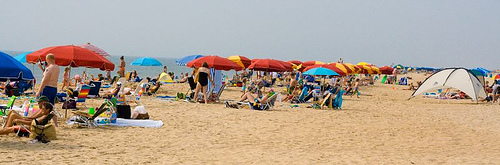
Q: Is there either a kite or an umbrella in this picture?
A: Yes, there is an umbrella.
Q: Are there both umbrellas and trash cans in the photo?
A: No, there is an umbrella but no trash cans.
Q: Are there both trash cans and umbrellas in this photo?
A: No, there is an umbrella but no trash cans.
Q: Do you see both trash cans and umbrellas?
A: No, there is an umbrella but no trash cans.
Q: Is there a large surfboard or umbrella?
A: Yes, there is a large umbrella.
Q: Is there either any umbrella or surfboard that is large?
A: Yes, the umbrella is large.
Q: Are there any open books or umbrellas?
A: Yes, there is an open umbrella.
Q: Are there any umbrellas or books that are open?
A: Yes, the umbrella is open.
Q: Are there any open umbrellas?
A: Yes, there is an open umbrella.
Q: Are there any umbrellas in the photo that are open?
A: Yes, there is an umbrella that is open.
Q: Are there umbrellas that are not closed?
A: Yes, there is a open umbrella.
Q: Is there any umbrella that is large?
A: Yes, there is an umbrella that is large.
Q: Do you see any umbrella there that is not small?
A: Yes, there is a large umbrella.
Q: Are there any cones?
A: No, there are no cones.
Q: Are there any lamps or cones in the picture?
A: No, there are no cones or lamps.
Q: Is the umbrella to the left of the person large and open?
A: Yes, the umbrella is large and open.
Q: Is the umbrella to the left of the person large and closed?
A: No, the umbrella is large but open.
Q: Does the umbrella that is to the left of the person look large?
A: Yes, the umbrella is large.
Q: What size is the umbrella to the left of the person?
A: The umbrella is large.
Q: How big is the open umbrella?
A: The umbrella is large.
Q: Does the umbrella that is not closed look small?
A: No, the umbrella is large.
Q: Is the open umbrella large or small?
A: The umbrella is large.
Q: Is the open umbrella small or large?
A: The umbrella is large.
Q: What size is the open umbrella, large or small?
A: The umbrella is large.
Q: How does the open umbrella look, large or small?
A: The umbrella is large.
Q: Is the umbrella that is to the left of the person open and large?
A: Yes, the umbrella is open and large.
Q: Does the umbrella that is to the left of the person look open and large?
A: Yes, the umbrella is open and large.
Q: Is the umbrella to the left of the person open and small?
A: No, the umbrella is open but large.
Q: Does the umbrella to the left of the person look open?
A: Yes, the umbrella is open.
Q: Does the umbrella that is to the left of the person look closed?
A: No, the umbrella is open.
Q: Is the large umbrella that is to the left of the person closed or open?
A: The umbrella is open.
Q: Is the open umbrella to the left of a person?
A: Yes, the umbrella is to the left of a person.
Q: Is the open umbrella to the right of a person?
A: No, the umbrella is to the left of a person.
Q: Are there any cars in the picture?
A: No, there are no cars.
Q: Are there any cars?
A: No, there are no cars.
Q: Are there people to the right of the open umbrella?
A: Yes, there is a person to the right of the umbrella.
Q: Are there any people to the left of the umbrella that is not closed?
A: No, the person is to the right of the umbrella.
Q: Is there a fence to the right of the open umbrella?
A: No, there is a person to the right of the umbrella.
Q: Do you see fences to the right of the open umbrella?
A: No, there is a person to the right of the umbrella.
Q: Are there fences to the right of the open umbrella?
A: No, there is a person to the right of the umbrella.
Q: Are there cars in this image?
A: No, there are no cars.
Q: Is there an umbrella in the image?
A: Yes, there is an umbrella.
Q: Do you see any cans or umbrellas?
A: Yes, there is an umbrella.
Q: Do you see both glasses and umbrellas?
A: No, there is an umbrella but no glasses.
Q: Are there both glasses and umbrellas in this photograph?
A: No, there is an umbrella but no glasses.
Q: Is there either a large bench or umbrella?
A: Yes, there is a large umbrella.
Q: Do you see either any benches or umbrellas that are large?
A: Yes, the umbrella is large.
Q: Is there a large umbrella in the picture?
A: Yes, there is a large umbrella.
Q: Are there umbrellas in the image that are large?
A: Yes, there is an umbrella that is large.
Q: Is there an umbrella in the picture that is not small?
A: Yes, there is a large umbrella.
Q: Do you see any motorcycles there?
A: No, there are no motorcycles.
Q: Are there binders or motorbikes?
A: No, there are no motorbikes or binders.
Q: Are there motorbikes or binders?
A: No, there are no motorbikes or binders.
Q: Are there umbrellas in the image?
A: Yes, there is an umbrella.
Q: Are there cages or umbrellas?
A: Yes, there is an umbrella.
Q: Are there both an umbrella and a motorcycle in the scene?
A: No, there is an umbrella but no motorcycles.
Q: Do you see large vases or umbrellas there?
A: Yes, there is a large umbrella.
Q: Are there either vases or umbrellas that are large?
A: Yes, the umbrella is large.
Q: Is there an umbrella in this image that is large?
A: Yes, there is a large umbrella.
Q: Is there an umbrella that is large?
A: Yes, there is an umbrella that is large.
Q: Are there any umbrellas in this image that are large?
A: Yes, there is an umbrella that is large.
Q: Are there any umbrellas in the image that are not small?
A: Yes, there is a large umbrella.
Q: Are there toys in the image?
A: No, there are no toys.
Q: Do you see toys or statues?
A: No, there are no toys or statues.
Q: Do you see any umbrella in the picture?
A: Yes, there is an umbrella.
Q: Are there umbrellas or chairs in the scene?
A: Yes, there is an umbrella.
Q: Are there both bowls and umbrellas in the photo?
A: No, there is an umbrella but no bowls.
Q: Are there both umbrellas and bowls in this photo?
A: No, there is an umbrella but no bowls.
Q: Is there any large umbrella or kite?
A: Yes, there is a large umbrella.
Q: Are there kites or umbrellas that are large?
A: Yes, the umbrella is large.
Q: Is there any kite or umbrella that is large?
A: Yes, the umbrella is large.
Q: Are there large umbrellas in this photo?
A: Yes, there is a large umbrella.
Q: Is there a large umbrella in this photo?
A: Yes, there is a large umbrella.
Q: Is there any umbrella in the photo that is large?
A: Yes, there is an umbrella that is large.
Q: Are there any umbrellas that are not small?
A: Yes, there is a large umbrella.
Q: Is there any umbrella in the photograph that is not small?
A: Yes, there is a large umbrella.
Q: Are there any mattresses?
A: No, there are no mattresses.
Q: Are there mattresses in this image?
A: No, there are no mattresses.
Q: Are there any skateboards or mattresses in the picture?
A: No, there are no mattresses or skateboards.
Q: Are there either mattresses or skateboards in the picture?
A: No, there are no mattresses or skateboards.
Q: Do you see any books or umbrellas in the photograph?
A: Yes, there is an umbrella.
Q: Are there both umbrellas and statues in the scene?
A: No, there is an umbrella but no statues.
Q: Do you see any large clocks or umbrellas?
A: Yes, there is a large umbrella.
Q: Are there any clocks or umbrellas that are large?
A: Yes, the umbrella is large.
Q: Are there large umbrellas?
A: Yes, there is a large umbrella.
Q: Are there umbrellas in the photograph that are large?
A: Yes, there is an umbrella that is large.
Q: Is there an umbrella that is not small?
A: Yes, there is a large umbrella.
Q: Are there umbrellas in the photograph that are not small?
A: Yes, there is a large umbrella.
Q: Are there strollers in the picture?
A: No, there are no strollers.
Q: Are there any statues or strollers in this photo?
A: No, there are no strollers or statues.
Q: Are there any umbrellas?
A: Yes, there is an umbrella.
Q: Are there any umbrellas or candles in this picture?
A: Yes, there is an umbrella.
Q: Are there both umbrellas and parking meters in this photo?
A: No, there is an umbrella but no parking meters.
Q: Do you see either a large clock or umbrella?
A: Yes, there is a large umbrella.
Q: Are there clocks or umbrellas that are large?
A: Yes, the umbrella is large.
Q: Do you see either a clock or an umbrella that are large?
A: Yes, the umbrella is large.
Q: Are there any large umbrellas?
A: Yes, there is a large umbrella.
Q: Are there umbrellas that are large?
A: Yes, there is an umbrella that is large.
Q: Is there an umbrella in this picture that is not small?
A: Yes, there is a large umbrella.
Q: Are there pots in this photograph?
A: No, there are no pots.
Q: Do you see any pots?
A: No, there are no pots.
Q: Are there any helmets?
A: No, there are no helmets.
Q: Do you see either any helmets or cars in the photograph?
A: No, there are no helmets or cars.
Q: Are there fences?
A: No, there are no fences.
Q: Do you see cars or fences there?
A: No, there are no fences or cars.